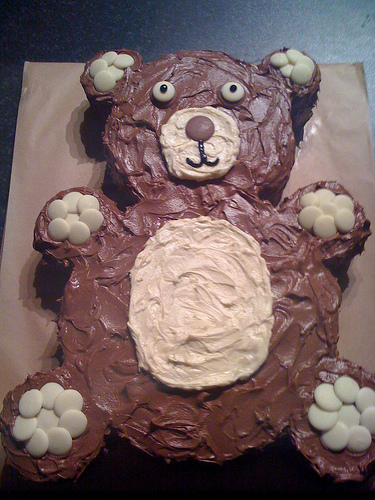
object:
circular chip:
[151, 80, 175, 103]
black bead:
[160, 84, 168, 93]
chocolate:
[313, 215, 337, 240]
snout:
[160, 105, 240, 183]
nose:
[185, 115, 214, 142]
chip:
[54, 407, 90, 440]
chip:
[50, 384, 84, 423]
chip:
[34, 382, 65, 412]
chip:
[15, 385, 46, 418]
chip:
[10, 412, 42, 444]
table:
[0, 0, 374, 499]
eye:
[221, 82, 244, 102]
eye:
[151, 79, 175, 102]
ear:
[79, 48, 141, 104]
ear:
[259, 47, 323, 108]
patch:
[128, 217, 274, 389]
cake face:
[98, 48, 299, 196]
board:
[0, 60, 375, 486]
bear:
[0, 47, 375, 483]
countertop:
[0, 0, 375, 263]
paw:
[32, 190, 124, 262]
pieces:
[47, 217, 71, 241]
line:
[198, 139, 205, 160]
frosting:
[182, 141, 204, 170]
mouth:
[185, 140, 220, 169]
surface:
[0, 0, 375, 247]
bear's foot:
[288, 352, 375, 484]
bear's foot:
[0, 365, 106, 485]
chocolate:
[185, 116, 212, 142]